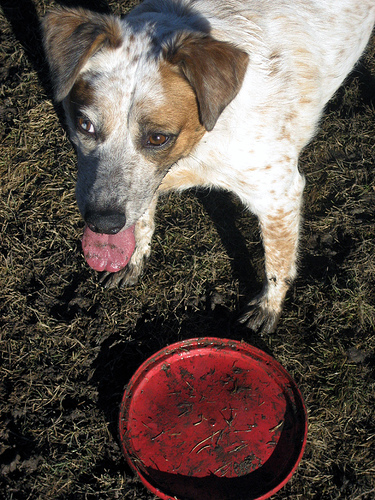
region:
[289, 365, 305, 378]
part of the grass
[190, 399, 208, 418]
part of a floater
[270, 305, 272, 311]
edge of a leg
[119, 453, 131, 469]
edge of a floater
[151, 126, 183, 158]
eye of a dog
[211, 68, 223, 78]
ear of a dog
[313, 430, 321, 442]
part of the grass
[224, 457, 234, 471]
part of a plastic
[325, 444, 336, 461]
part of the lawn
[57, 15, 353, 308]
a dog standing in the mud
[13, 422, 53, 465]
black mud of the ground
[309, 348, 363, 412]
green muddy grass of the ground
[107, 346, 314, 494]
dirty red frisbee on the ground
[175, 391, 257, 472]
dead grass and mud on the frisbee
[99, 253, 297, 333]
muddy front paws of the ground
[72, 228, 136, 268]
pink tongue hanging out of the dogs mouth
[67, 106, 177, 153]
brown eyes of the dog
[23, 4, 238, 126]
floppy brown ears of the dog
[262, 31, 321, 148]
brown spots in the dogs white fur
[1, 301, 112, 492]
short, muddy grass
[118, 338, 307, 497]
red muddy lid or dog dish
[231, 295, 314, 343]
muddy dog's paw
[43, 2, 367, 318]
muddy dog panting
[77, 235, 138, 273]
pink tongue of dog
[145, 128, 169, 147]
dog's brown eye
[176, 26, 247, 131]
floppy ear of dog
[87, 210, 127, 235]
dog's black nose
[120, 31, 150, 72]
white dog fur with small brown spots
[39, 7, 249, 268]
head of panting dog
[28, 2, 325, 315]
a dog standing in the grass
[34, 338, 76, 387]
brown mud of the ground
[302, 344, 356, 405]
green grass on the ground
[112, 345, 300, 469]
a dirty red frisbee on the ground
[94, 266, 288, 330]
muddy front paws of the dog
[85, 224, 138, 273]
pink tongue hanging out of the dog's mouth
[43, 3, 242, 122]
brown floppy ears of the dog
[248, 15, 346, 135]
brown spots in the dogs white fur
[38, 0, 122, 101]
dog has brown ear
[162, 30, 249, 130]
brown ear on dog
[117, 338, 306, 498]
dirty red plate on ground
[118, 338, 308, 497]
red plate is dirty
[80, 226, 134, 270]
the dog has a pink tongue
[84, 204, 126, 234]
dog has black nose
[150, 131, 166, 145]
dog has brown eye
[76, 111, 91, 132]
dog has brown eye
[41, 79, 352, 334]
dog is brown and white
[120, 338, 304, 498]
red plate under dog